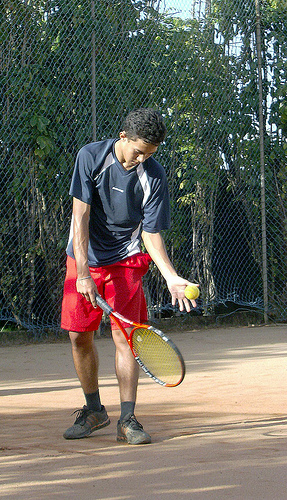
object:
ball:
[184, 285, 200, 301]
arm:
[140, 174, 178, 280]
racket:
[93, 294, 186, 389]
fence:
[1, 1, 287, 337]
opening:
[0, 298, 277, 342]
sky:
[0, 1, 287, 177]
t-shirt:
[66, 136, 170, 268]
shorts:
[59, 249, 152, 335]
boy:
[59, 107, 200, 445]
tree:
[206, 1, 279, 321]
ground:
[0, 316, 287, 496]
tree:
[176, 18, 239, 319]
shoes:
[63, 401, 111, 440]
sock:
[119, 399, 137, 422]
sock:
[84, 386, 103, 411]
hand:
[166, 276, 201, 313]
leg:
[62, 254, 111, 441]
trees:
[1, 0, 44, 331]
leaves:
[100, 14, 135, 90]